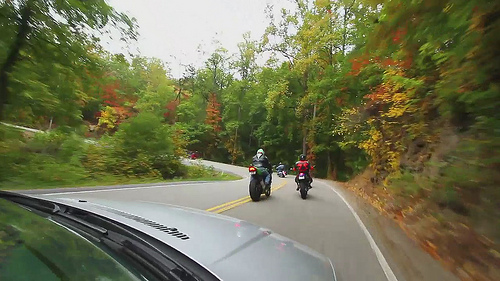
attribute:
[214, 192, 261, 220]
line — yellow, double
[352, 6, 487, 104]
leaves — changing color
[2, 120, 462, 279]
road — curving to left, curvyy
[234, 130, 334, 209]
objects — blurry 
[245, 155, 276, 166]
jacket — black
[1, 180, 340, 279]
car —  silver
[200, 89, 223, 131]
leaves — orange, autumn leaves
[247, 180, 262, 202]
tire — back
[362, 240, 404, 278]
line — white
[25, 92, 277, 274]
car — gray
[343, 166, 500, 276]
ground — Brown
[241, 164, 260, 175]
light — tail, red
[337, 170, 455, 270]
bananas — green, unripe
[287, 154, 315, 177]
jacket — red, black